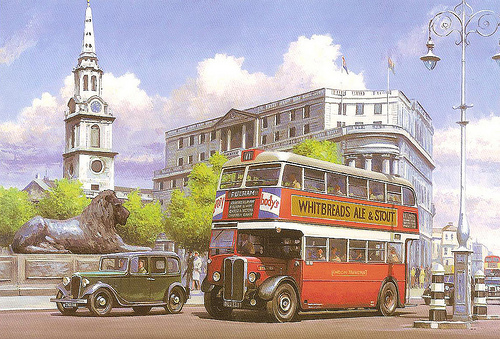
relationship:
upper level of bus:
[208, 149, 426, 235] [193, 143, 430, 325]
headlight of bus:
[248, 270, 256, 280] [202, 145, 419, 318]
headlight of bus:
[209, 269, 223, 281] [202, 145, 419, 318]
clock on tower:
[89, 98, 103, 114] [56, 12, 130, 189]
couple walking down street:
[182, 250, 202, 292] [2, 298, 498, 336]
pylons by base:
[423, 257, 450, 324] [451, 245, 477, 321]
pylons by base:
[468, 262, 488, 322] [451, 245, 477, 321]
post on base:
[450, 2, 485, 323] [451, 245, 477, 321]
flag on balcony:
[340, 56, 347, 71] [164, 88, 434, 140]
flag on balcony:
[382, 53, 397, 73] [164, 88, 434, 140]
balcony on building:
[164, 88, 434, 140] [154, 88, 436, 285]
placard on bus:
[226, 193, 260, 219] [202, 145, 419, 318]